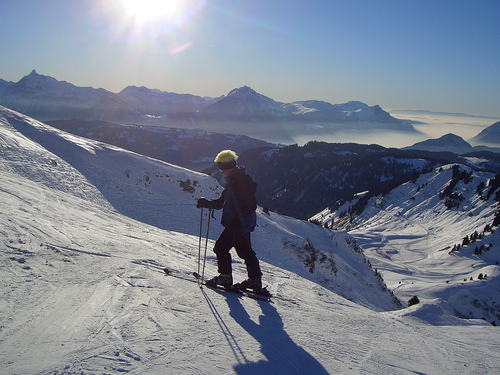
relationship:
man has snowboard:
[197, 150, 262, 291] [162, 261, 312, 304]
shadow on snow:
[192, 287, 290, 354] [0, 104, 500, 370]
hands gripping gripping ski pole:
[186, 181, 211, 211] [200, 201, 215, 280]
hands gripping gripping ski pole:
[186, 181, 211, 211] [193, 204, 206, 281]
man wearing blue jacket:
[197, 150, 262, 291] [197, 170, 278, 235]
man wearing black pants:
[212, 221, 267, 293] [211, 216, 267, 283]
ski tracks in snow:
[89, 256, 185, 371] [0, 104, 500, 370]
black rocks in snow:
[271, 219, 396, 310] [0, 104, 500, 370]